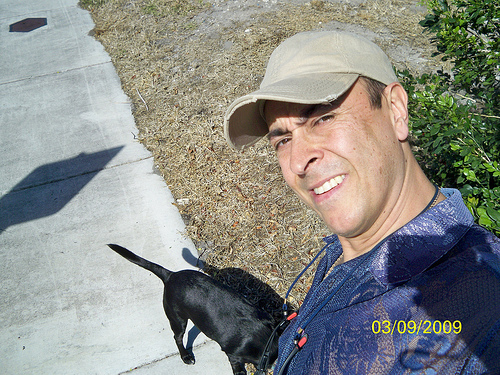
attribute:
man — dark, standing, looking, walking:
[245, 46, 460, 271]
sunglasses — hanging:
[275, 300, 314, 356]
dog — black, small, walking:
[141, 275, 270, 353]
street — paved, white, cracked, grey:
[34, 101, 117, 199]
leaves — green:
[436, 42, 485, 120]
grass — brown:
[144, 18, 206, 59]